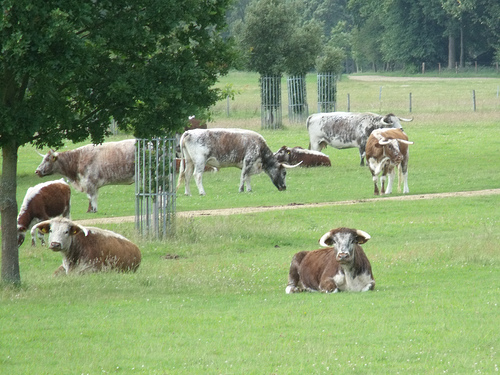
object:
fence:
[224, 89, 477, 116]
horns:
[319, 232, 331, 247]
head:
[318, 226, 371, 264]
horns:
[356, 230, 370, 240]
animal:
[364, 127, 411, 196]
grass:
[13, 68, 481, 371]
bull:
[177, 128, 302, 196]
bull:
[31, 213, 139, 268]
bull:
[34, 138, 136, 213]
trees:
[241, 0, 298, 130]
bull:
[285, 227, 375, 295]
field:
[4, 110, 498, 373]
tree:
[0, 6, 226, 322]